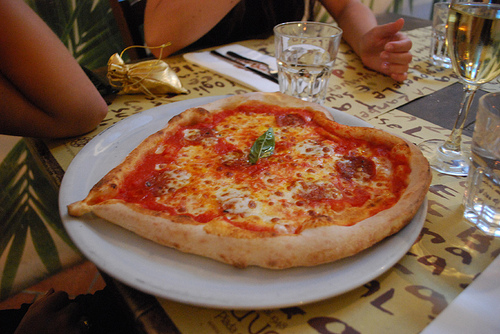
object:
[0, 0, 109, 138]
arms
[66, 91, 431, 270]
individual pizza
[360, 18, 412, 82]
hand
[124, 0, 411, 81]
person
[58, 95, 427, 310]
plate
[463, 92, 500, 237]
glass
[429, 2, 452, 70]
glass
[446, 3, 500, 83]
wine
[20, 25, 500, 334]
table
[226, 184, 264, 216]
cheese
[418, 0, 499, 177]
glass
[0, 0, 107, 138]
woman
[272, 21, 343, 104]
glass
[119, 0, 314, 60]
dress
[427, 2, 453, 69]
cup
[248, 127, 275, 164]
leaf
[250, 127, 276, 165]
oregano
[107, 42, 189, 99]
bag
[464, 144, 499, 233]
water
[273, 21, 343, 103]
cup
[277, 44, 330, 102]
water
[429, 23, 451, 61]
water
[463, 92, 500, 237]
cup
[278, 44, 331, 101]
liquid